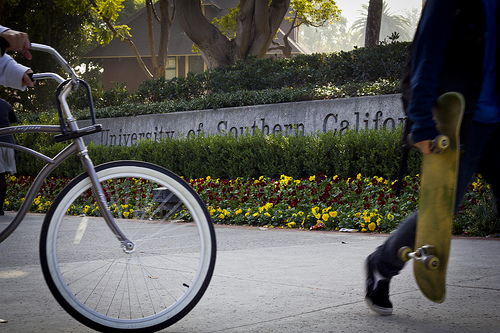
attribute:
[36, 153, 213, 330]
tire — black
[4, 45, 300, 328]
bicycle — silver, gray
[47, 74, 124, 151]
lock — black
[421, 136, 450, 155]
wheel — white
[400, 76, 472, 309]
skateboard — yellow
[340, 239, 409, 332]
shoe — tennis, black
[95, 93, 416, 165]
signs — concrete, university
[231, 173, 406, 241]
flowers — red, yellow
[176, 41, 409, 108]
bushes — green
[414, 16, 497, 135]
shirt — dark